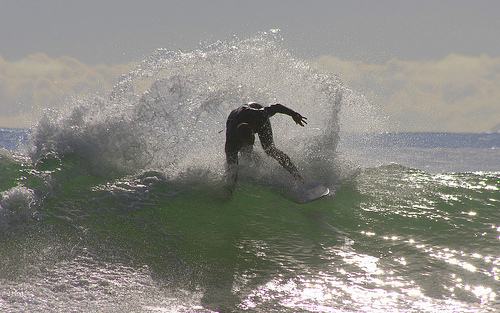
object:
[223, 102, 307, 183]
wetsuit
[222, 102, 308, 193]
person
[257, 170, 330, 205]
surfboard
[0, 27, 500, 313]
water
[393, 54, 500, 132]
cloud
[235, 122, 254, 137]
hair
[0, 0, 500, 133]
sky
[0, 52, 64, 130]
cloud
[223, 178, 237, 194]
hand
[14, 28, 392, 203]
wave